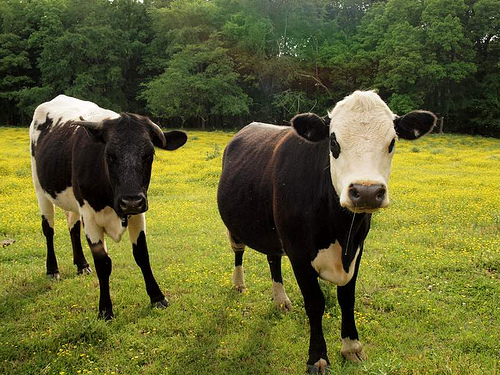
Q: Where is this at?
A: A field.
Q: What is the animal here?
A: Cow.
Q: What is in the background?
A: Trees.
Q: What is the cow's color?
A: White and black.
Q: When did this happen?
A: During the day time.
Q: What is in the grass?
A: Flower.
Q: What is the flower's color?
A: Yellow.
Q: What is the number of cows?
A: 2.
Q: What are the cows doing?
A: Standing.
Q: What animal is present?
A: Cow.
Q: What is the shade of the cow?
A: Black and white.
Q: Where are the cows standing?
A: On grass.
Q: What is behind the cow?
A: Field.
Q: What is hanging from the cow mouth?
A: Saliva.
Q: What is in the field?
A: Tree.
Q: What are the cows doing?
A: Standing.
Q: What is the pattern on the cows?
A: Black and white.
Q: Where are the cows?
A: In a field.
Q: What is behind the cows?
A: Trees.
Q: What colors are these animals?
A: Black and white.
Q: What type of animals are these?
A: Cows.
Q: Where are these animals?
A: On the grass.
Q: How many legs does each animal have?
A: Four.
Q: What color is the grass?
A: Green.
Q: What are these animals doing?
A: Standing.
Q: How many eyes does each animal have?
A: Two.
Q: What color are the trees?
A: Green.